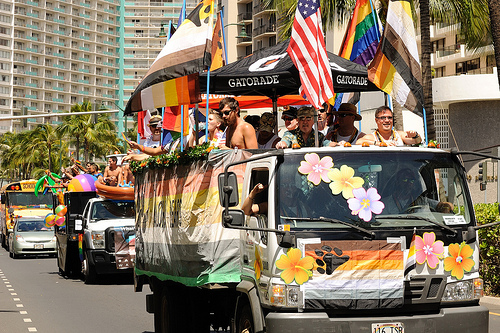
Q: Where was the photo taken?
A: It was taken at the street.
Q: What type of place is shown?
A: It is a street.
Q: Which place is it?
A: It is a street.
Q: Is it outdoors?
A: Yes, it is outdoors.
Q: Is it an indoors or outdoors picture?
A: It is outdoors.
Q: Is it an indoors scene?
A: No, it is outdoors.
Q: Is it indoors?
A: No, it is outdoors.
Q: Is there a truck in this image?
A: Yes, there is a truck.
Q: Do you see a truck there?
A: Yes, there is a truck.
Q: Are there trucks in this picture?
A: Yes, there is a truck.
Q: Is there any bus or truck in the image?
A: Yes, there is a truck.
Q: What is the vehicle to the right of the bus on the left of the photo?
A: The vehicle is a truck.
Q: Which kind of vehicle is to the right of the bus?
A: The vehicle is a truck.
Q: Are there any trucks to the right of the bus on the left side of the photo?
A: Yes, there is a truck to the right of the bus.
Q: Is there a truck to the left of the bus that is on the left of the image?
A: No, the truck is to the right of the bus.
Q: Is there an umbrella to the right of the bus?
A: No, there is a truck to the right of the bus.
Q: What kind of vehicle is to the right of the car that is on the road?
A: The vehicle is a truck.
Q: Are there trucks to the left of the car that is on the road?
A: No, the truck is to the right of the car.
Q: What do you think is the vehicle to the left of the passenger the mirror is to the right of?
A: The vehicle is a truck.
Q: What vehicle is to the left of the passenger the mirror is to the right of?
A: The vehicle is a truck.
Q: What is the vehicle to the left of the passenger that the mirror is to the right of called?
A: The vehicle is a truck.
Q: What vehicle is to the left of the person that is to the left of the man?
A: The vehicle is a truck.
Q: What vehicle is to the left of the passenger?
A: The vehicle is a truck.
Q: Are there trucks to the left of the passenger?
A: Yes, there is a truck to the left of the passenger.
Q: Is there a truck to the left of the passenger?
A: Yes, there is a truck to the left of the passenger.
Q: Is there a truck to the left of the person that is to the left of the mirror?
A: Yes, there is a truck to the left of the passenger.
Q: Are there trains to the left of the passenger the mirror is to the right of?
A: No, there is a truck to the left of the passenger.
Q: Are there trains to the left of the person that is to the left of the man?
A: No, there is a truck to the left of the passenger.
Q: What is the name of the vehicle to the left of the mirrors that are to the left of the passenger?
A: The vehicle is a truck.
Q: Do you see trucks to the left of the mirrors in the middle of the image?
A: Yes, there is a truck to the left of the mirrors.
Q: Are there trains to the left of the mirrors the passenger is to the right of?
A: No, there is a truck to the left of the mirrors.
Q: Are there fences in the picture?
A: No, there are no fences.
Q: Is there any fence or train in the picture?
A: No, there are no fences or trains.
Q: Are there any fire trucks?
A: No, there are no fire trucks.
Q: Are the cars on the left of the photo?
A: Yes, the cars are on the left of the image.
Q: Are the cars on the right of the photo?
A: No, the cars are on the left of the image.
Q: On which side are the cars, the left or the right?
A: The cars are on the left of the image.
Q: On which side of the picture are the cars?
A: The cars are on the left of the image.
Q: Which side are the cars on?
A: The cars are on the left of the image.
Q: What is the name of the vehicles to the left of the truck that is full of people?
A: The vehicles are cars.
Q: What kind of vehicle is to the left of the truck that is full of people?
A: The vehicles are cars.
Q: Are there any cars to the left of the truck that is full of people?
A: Yes, there are cars to the left of the truck.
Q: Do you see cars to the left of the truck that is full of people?
A: Yes, there are cars to the left of the truck.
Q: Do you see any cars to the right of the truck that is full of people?
A: No, the cars are to the left of the truck.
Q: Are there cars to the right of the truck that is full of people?
A: No, the cars are to the left of the truck.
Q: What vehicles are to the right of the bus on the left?
A: The vehicles are cars.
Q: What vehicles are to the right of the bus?
A: The vehicles are cars.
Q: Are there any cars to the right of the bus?
A: Yes, there are cars to the right of the bus.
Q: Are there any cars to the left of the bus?
A: No, the cars are to the right of the bus.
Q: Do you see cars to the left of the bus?
A: No, the cars are to the right of the bus.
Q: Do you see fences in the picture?
A: No, there are no fences.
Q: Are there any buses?
A: Yes, there is a bus.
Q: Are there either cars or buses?
A: Yes, there is a bus.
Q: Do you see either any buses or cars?
A: Yes, there is a bus.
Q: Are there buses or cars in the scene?
A: Yes, there is a bus.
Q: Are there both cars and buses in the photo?
A: Yes, there are both a bus and a car.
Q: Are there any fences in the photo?
A: No, there are no fences.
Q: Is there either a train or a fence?
A: No, there are no fences or trains.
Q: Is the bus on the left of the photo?
A: Yes, the bus is on the left of the image.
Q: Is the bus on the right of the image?
A: No, the bus is on the left of the image.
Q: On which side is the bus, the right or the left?
A: The bus is on the left of the image.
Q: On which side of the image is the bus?
A: The bus is on the left of the image.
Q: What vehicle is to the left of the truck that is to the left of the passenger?
A: The vehicle is a bus.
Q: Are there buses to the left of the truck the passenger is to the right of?
A: Yes, there is a bus to the left of the truck.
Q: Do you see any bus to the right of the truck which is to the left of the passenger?
A: No, the bus is to the left of the truck.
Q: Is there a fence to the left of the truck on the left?
A: No, there is a bus to the left of the truck.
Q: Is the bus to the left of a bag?
A: No, the bus is to the left of a truck.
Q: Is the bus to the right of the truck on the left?
A: No, the bus is to the left of the truck.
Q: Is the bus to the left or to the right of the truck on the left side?
A: The bus is to the left of the truck.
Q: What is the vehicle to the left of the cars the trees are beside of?
A: The vehicle is a bus.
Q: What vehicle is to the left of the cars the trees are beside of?
A: The vehicle is a bus.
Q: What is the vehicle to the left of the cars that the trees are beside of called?
A: The vehicle is a bus.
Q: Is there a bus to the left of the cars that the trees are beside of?
A: Yes, there is a bus to the left of the cars.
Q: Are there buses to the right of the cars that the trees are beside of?
A: No, the bus is to the left of the cars.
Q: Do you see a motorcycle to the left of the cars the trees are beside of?
A: No, there is a bus to the left of the cars.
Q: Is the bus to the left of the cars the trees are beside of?
A: Yes, the bus is to the left of the cars.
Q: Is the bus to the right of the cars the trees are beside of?
A: No, the bus is to the left of the cars.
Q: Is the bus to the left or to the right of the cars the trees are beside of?
A: The bus is to the left of the cars.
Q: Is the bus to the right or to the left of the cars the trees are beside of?
A: The bus is to the left of the cars.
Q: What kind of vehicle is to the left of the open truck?
A: The vehicle is a bus.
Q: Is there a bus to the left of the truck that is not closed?
A: Yes, there is a bus to the left of the truck.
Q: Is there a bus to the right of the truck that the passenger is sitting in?
A: No, the bus is to the left of the truck.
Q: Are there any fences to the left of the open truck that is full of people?
A: No, there is a bus to the left of the truck.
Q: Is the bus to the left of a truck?
A: Yes, the bus is to the left of a truck.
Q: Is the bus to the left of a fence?
A: No, the bus is to the left of a truck.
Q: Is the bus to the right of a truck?
A: No, the bus is to the left of a truck.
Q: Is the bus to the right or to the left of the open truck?
A: The bus is to the left of the truck.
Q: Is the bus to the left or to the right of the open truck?
A: The bus is to the left of the truck.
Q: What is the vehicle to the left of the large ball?
A: The vehicle is a bus.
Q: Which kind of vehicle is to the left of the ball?
A: The vehicle is a bus.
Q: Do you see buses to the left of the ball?
A: Yes, there is a bus to the left of the ball.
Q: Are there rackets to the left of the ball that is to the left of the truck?
A: No, there is a bus to the left of the ball.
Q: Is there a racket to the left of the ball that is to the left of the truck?
A: No, there is a bus to the left of the ball.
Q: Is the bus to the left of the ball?
A: Yes, the bus is to the left of the ball.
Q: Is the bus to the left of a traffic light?
A: No, the bus is to the left of the ball.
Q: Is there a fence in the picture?
A: No, there are no fences.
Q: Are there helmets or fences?
A: No, there are no fences or helmets.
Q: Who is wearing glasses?
A: The man is wearing glasses.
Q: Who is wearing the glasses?
A: The man is wearing glasses.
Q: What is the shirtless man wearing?
A: The man is wearing glasses.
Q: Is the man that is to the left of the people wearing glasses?
A: Yes, the man is wearing glasses.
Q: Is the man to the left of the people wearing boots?
A: No, the man is wearing glasses.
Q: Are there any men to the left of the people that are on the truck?
A: Yes, there is a man to the left of the people.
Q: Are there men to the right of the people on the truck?
A: No, the man is to the left of the people.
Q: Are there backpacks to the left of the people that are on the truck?
A: No, there is a man to the left of the people.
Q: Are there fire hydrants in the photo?
A: No, there are no fire hydrants.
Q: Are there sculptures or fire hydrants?
A: No, there are no fire hydrants or sculptures.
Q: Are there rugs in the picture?
A: No, there are no rugs.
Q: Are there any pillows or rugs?
A: No, there are no rugs or pillows.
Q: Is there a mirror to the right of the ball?
A: Yes, there are mirrors to the right of the ball.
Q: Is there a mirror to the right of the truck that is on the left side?
A: Yes, there are mirrors to the right of the truck.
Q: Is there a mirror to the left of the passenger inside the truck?
A: Yes, there are mirrors to the left of the passenger.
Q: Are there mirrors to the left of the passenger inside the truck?
A: Yes, there are mirrors to the left of the passenger.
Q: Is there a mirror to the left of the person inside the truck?
A: Yes, there are mirrors to the left of the passenger.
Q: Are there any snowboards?
A: No, there are no snowboards.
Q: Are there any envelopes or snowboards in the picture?
A: No, there are no snowboards or envelopes.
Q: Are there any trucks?
A: Yes, there is a truck.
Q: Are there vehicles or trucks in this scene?
A: Yes, there is a truck.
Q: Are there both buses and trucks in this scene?
A: Yes, there are both a truck and a bus.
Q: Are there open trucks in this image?
A: Yes, there is an open truck.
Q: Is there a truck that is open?
A: Yes, there is a truck that is open.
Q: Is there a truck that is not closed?
A: Yes, there is a open truck.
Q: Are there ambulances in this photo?
A: No, there are no ambulances.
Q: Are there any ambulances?
A: No, there are no ambulances.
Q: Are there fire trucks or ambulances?
A: No, there are no ambulances or fire trucks.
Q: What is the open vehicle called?
A: The vehicle is a truck.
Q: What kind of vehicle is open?
A: The vehicle is a truck.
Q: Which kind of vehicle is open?
A: The vehicle is a truck.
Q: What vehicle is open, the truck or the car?
A: The truck is open.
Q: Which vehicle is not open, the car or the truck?
A: The car is not open.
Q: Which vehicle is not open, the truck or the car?
A: The car is not open.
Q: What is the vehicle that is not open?
A: The vehicle is a car.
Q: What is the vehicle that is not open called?
A: The vehicle is a car.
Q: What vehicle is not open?
A: The vehicle is a car.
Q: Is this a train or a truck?
A: This is a truck.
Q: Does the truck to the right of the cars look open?
A: Yes, the truck is open.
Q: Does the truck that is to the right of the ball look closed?
A: No, the truck is open.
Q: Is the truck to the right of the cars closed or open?
A: The truck is open.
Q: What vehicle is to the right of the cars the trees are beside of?
A: The vehicle is a truck.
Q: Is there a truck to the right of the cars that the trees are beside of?
A: Yes, there is a truck to the right of the cars.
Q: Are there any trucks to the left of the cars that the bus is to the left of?
A: No, the truck is to the right of the cars.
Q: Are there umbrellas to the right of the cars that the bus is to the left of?
A: No, there is a truck to the right of the cars.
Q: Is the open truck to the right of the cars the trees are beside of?
A: Yes, the truck is to the right of the cars.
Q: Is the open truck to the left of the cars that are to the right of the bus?
A: No, the truck is to the right of the cars.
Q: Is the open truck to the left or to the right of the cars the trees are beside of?
A: The truck is to the right of the cars.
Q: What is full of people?
A: The truck is full of people.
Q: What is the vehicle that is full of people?
A: The vehicle is a truck.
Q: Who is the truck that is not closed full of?
A: The truck is full of people.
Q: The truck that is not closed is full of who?
A: The truck is full of people.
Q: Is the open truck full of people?
A: Yes, the truck is full of people.